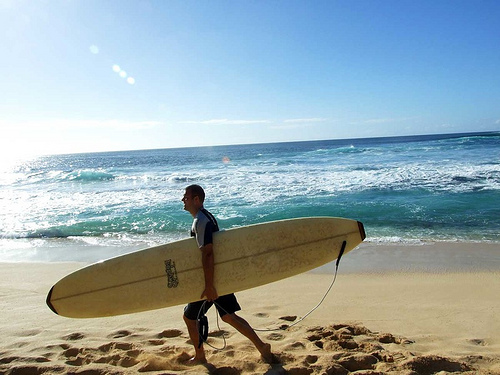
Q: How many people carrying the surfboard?
A: One.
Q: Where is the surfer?
A: At the beach.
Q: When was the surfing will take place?
A: In daytime.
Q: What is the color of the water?
A: Bluegreen.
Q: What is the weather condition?
A: Warm.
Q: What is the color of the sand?
A: Brown.